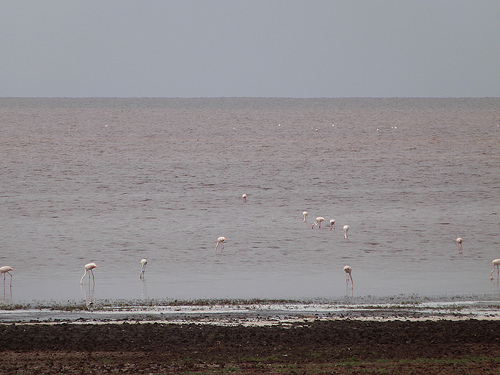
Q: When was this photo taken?
A: In the daytime.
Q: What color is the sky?
A: Blue.